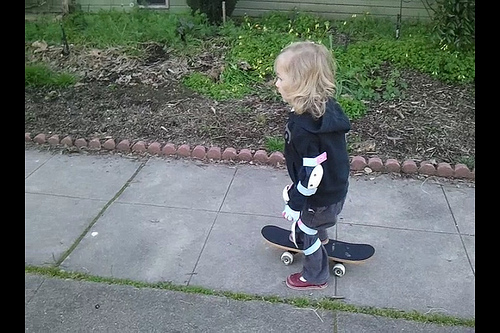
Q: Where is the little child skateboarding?
A: Sidewalk.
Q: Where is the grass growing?
A: Edge of the sidewalk.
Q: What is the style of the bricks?
A: Scalloped.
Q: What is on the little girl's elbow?
A: An elbow pad.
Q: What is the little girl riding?
A: A skateboard.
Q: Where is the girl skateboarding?
A: On the sidewalk.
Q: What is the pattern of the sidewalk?
A: Squares.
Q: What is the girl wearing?
A: A black hoodie and pants.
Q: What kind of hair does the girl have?
A: Curly blonde.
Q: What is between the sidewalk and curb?
A: Thin line of grass.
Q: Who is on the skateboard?
A: Little girl.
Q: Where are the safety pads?
A: Elbows and knees.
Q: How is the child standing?
A: One foot on skateboard.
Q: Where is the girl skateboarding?
A: Sidewalk.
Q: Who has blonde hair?
A: Toddler.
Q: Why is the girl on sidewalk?
A: Skateboarding.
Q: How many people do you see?
A: 1.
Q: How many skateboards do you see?
A: One.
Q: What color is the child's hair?
A: Blonde.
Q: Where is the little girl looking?
A: To the left.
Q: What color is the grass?
A: Green.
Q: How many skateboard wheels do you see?
A: 2.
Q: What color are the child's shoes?
A: Red.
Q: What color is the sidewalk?
A: Grey.